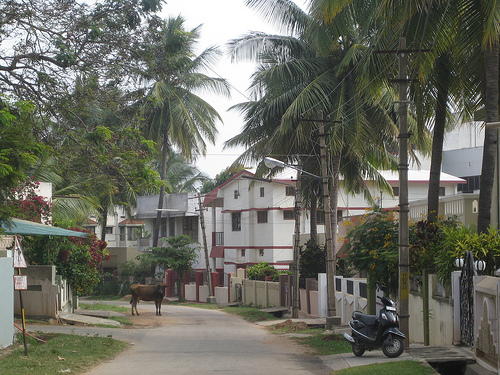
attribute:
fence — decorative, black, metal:
[313, 272, 497, 354]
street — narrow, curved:
[89, 299, 325, 374]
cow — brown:
[121, 271, 178, 313]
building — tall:
[439, 147, 483, 207]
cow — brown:
[126, 280, 166, 316]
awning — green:
[3, 213, 92, 240]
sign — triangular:
[14, 234, 28, 268]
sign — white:
[12, 235, 27, 268]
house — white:
[135, 137, 460, 374]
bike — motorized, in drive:
[327, 297, 414, 348]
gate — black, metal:
[456, 245, 478, 347]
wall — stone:
[407, 245, 499, 372]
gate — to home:
[452, 256, 484, 345]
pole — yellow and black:
[10, 266, 31, 354]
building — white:
[201, 169, 326, 305]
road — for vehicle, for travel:
[138, 296, 311, 373]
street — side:
[15, 322, 127, 346]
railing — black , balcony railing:
[210, 228, 222, 243]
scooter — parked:
[344, 295, 414, 359]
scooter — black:
[340, 295, 405, 357]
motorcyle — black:
[350, 295, 411, 360]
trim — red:
[216, 204, 288, 212]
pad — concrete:
[332, 340, 461, 364]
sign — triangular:
[3, 229, 38, 289]